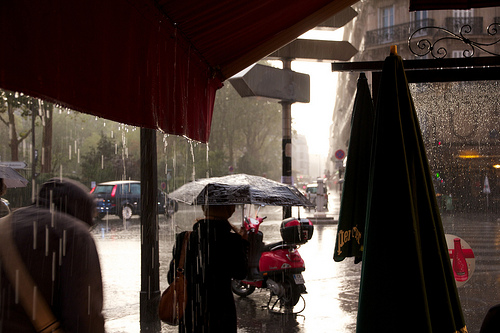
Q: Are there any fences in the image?
A: No, there are no fences.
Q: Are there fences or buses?
A: No, there are no fences or buses.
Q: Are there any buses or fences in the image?
A: No, there are no fences or buses.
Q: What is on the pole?
A: The sign is on the pole.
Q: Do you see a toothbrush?
A: No, there are no toothbrushes.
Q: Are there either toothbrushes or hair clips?
A: No, there are no toothbrushes or hair clips.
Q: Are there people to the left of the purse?
A: Yes, there is a person to the left of the purse.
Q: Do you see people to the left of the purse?
A: Yes, there is a person to the left of the purse.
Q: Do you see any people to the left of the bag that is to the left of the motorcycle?
A: Yes, there is a person to the left of the purse.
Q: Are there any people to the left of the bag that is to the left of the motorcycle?
A: Yes, there is a person to the left of the purse.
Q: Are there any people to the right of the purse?
A: No, the person is to the left of the purse.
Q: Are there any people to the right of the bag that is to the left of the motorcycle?
A: No, the person is to the left of the purse.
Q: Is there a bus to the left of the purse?
A: No, there is a person to the left of the purse.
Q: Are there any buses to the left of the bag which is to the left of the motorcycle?
A: No, there is a person to the left of the purse.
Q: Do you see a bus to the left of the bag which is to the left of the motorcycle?
A: No, there is a person to the left of the purse.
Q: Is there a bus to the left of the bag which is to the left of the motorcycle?
A: No, there is a person to the left of the purse.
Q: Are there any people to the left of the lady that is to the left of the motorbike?
A: Yes, there is a person to the left of the lady.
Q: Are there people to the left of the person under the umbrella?
A: Yes, there is a person to the left of the lady.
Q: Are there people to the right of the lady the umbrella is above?
A: No, the person is to the left of the lady.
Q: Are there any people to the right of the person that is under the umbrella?
A: No, the person is to the left of the lady.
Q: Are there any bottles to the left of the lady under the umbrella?
A: No, there is a person to the left of the lady.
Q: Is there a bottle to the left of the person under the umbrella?
A: No, there is a person to the left of the lady.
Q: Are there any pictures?
A: No, there are no pictures.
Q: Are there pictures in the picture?
A: No, there are no pictures.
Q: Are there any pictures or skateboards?
A: No, there are no pictures or skateboards.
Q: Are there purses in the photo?
A: Yes, there is a purse.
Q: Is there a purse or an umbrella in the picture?
A: Yes, there is a purse.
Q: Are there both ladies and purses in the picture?
A: Yes, there are both a purse and a lady.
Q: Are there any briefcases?
A: No, there are no briefcases.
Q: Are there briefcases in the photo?
A: No, there are no briefcases.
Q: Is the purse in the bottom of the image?
A: Yes, the purse is in the bottom of the image.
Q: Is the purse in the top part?
A: No, the purse is in the bottom of the image.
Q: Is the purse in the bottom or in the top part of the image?
A: The purse is in the bottom of the image.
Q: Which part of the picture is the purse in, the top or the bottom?
A: The purse is in the bottom of the image.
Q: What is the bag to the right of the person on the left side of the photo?
A: The bag is a purse.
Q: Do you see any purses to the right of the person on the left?
A: Yes, there is a purse to the right of the person.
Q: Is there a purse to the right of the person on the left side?
A: Yes, there is a purse to the right of the person.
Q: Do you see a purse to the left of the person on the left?
A: No, the purse is to the right of the person.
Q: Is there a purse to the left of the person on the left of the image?
A: No, the purse is to the right of the person.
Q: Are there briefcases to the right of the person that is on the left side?
A: No, there is a purse to the right of the person.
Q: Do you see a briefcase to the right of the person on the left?
A: No, there is a purse to the right of the person.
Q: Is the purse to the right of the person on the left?
A: Yes, the purse is to the right of the person.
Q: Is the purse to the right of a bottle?
A: No, the purse is to the right of the person.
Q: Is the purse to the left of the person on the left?
A: No, the purse is to the right of the person.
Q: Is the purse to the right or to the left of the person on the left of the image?
A: The purse is to the right of the person.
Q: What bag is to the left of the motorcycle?
A: The bag is a purse.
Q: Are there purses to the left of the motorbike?
A: Yes, there is a purse to the left of the motorbike.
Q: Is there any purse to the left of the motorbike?
A: Yes, there is a purse to the left of the motorbike.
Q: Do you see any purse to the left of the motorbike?
A: Yes, there is a purse to the left of the motorbike.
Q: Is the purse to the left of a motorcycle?
A: Yes, the purse is to the left of a motorcycle.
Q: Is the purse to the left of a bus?
A: No, the purse is to the left of a motorcycle.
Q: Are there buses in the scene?
A: No, there are no buses.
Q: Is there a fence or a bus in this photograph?
A: No, there are no buses or fences.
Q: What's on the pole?
A: The sign is on the pole.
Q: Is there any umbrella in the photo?
A: Yes, there is an umbrella.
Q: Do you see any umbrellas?
A: Yes, there is an umbrella.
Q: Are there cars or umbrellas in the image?
A: Yes, there is an umbrella.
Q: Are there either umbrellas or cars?
A: Yes, there is an umbrella.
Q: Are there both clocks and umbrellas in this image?
A: No, there is an umbrella but no clocks.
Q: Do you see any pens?
A: No, there are no pens.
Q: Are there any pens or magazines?
A: No, there are no pens or magazines.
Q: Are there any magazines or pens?
A: No, there are no pens or magazines.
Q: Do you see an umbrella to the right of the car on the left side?
A: Yes, there is an umbrella to the right of the car.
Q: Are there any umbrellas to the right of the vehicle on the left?
A: Yes, there is an umbrella to the right of the car.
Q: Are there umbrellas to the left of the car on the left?
A: No, the umbrella is to the right of the car.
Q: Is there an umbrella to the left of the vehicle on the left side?
A: No, the umbrella is to the right of the car.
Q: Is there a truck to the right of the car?
A: No, there is an umbrella to the right of the car.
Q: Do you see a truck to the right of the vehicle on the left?
A: No, there is an umbrella to the right of the car.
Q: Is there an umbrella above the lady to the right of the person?
A: Yes, there is an umbrella above the lady.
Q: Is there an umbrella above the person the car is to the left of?
A: Yes, there is an umbrella above the lady.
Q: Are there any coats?
A: Yes, there is a coat.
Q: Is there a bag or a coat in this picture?
A: Yes, there is a coat.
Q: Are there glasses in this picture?
A: No, there are no glasses.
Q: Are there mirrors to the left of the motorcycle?
A: No, there is a lady to the left of the motorcycle.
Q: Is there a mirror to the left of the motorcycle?
A: No, there is a lady to the left of the motorcycle.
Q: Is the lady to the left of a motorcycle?
A: Yes, the lady is to the left of a motorcycle.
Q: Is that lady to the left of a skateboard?
A: No, the lady is to the left of a motorcycle.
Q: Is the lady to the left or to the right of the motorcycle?
A: The lady is to the left of the motorcycle.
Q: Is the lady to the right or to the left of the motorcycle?
A: The lady is to the left of the motorcycle.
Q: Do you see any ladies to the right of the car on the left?
A: Yes, there is a lady to the right of the car.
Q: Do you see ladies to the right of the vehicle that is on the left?
A: Yes, there is a lady to the right of the car.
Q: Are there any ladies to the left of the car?
A: No, the lady is to the right of the car.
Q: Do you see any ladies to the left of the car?
A: No, the lady is to the right of the car.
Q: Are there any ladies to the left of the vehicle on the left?
A: No, the lady is to the right of the car.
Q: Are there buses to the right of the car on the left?
A: No, there is a lady to the right of the car.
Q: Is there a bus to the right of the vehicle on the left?
A: No, there is a lady to the right of the car.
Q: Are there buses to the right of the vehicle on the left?
A: No, there is a lady to the right of the car.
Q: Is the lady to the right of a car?
A: Yes, the lady is to the right of a car.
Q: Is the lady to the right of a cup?
A: No, the lady is to the right of a car.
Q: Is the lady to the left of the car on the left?
A: No, the lady is to the right of the car.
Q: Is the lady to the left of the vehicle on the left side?
A: No, the lady is to the right of the car.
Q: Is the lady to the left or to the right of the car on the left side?
A: The lady is to the right of the car.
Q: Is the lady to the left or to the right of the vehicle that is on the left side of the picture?
A: The lady is to the right of the car.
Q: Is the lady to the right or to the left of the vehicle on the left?
A: The lady is to the right of the car.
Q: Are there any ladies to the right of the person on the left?
A: Yes, there is a lady to the right of the person.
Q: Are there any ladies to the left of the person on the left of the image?
A: No, the lady is to the right of the person.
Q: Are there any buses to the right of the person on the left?
A: No, there is a lady to the right of the person.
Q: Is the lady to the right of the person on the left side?
A: Yes, the lady is to the right of the person.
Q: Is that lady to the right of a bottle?
A: No, the lady is to the right of the person.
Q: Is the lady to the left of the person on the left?
A: No, the lady is to the right of the person.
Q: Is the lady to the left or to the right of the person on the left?
A: The lady is to the right of the person.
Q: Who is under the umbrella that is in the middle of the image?
A: The lady is under the umbrella.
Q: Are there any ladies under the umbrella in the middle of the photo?
A: Yes, there is a lady under the umbrella.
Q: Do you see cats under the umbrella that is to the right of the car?
A: No, there is a lady under the umbrella.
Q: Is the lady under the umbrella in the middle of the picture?
A: Yes, the lady is under the umbrella.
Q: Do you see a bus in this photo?
A: No, there are no buses.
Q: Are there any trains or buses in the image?
A: No, there are no buses or trains.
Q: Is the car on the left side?
A: Yes, the car is on the left of the image.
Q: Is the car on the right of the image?
A: No, the car is on the left of the image.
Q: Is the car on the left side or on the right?
A: The car is on the left of the image.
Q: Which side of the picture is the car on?
A: The car is on the left of the image.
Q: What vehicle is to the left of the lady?
A: The vehicle is a car.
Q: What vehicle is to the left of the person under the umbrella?
A: The vehicle is a car.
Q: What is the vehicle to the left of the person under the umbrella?
A: The vehicle is a car.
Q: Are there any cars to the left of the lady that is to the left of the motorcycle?
A: Yes, there is a car to the left of the lady.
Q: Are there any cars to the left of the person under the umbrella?
A: Yes, there is a car to the left of the lady.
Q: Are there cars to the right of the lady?
A: No, the car is to the left of the lady.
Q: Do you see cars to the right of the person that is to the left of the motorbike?
A: No, the car is to the left of the lady.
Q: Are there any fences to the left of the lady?
A: No, there is a car to the left of the lady.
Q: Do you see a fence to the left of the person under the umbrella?
A: No, there is a car to the left of the lady.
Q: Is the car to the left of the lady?
A: Yes, the car is to the left of the lady.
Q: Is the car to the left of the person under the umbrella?
A: Yes, the car is to the left of the lady.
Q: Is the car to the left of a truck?
A: No, the car is to the left of the lady.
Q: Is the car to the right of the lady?
A: No, the car is to the left of the lady.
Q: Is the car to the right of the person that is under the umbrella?
A: No, the car is to the left of the lady.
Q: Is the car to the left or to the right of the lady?
A: The car is to the left of the lady.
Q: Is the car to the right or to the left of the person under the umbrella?
A: The car is to the left of the lady.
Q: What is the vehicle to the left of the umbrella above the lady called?
A: The vehicle is a car.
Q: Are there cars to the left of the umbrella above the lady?
A: Yes, there is a car to the left of the umbrella.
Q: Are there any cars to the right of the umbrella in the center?
A: No, the car is to the left of the umbrella.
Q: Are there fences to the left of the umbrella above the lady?
A: No, there is a car to the left of the umbrella.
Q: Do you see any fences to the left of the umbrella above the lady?
A: No, there is a car to the left of the umbrella.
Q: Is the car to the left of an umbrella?
A: Yes, the car is to the left of an umbrella.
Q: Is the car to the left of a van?
A: No, the car is to the left of an umbrella.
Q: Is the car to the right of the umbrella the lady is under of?
A: No, the car is to the left of the umbrella.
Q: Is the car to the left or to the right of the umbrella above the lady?
A: The car is to the left of the umbrella.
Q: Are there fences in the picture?
A: No, there are no fences.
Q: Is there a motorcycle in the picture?
A: Yes, there is a motorcycle.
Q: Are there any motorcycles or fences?
A: Yes, there is a motorcycle.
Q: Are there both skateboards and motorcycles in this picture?
A: No, there is a motorcycle but no skateboards.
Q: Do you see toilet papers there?
A: No, there are no toilet papers.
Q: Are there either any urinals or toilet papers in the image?
A: No, there are no toilet papers or urinals.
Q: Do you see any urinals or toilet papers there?
A: No, there are no toilet papers or urinals.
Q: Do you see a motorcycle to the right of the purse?
A: Yes, there is a motorcycle to the right of the purse.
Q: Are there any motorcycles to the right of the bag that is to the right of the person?
A: Yes, there is a motorcycle to the right of the purse.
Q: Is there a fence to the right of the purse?
A: No, there is a motorcycle to the right of the purse.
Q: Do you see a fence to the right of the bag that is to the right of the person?
A: No, there is a motorcycle to the right of the purse.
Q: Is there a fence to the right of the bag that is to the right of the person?
A: No, there is a motorcycle to the right of the purse.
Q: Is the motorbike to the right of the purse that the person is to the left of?
A: Yes, the motorbike is to the right of the purse.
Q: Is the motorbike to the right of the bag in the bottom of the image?
A: Yes, the motorbike is to the right of the purse.